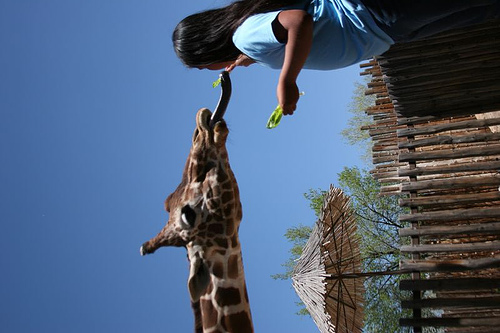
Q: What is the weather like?
A: It is clear.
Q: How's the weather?
A: It is clear.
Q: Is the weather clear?
A: Yes, it is clear.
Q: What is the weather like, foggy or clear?
A: It is clear.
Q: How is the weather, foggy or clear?
A: It is clear.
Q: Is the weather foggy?
A: No, it is clear.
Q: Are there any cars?
A: No, there are no cars.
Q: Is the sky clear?
A: Yes, the sky is clear.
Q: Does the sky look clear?
A: Yes, the sky is clear.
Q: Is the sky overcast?
A: No, the sky is clear.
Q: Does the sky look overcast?
A: No, the sky is clear.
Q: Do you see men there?
A: No, there are no men.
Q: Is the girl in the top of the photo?
A: Yes, the girl is in the top of the image.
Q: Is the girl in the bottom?
A: No, the girl is in the top of the image.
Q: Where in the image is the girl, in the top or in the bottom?
A: The girl is in the top of the image.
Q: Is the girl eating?
A: Yes, the girl is eating.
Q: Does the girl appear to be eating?
A: Yes, the girl is eating.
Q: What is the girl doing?
A: The girl is eating.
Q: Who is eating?
A: The girl is eating.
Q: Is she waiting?
A: No, the girl is eating.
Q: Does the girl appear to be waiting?
A: No, the girl is eating.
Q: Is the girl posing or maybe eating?
A: The girl is eating.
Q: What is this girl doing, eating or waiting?
A: The girl is eating.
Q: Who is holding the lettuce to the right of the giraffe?
A: The girl is holding the lettuce.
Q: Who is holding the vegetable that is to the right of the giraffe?
A: The girl is holding the lettuce.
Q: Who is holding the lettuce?
A: The girl is holding the lettuce.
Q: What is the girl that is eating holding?
A: The girl is holding the lettuce.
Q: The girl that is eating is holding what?
A: The girl is holding the lettuce.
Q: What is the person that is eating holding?
A: The girl is holding the lettuce.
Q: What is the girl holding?
A: The girl is holding the lettuce.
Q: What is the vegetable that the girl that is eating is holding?
A: The vegetable is lettuce.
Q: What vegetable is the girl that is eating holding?
A: The girl is holding the lettuce.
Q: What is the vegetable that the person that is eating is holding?
A: The vegetable is lettuce.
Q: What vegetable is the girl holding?
A: The girl is holding the lettuce.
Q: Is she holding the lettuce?
A: Yes, the girl is holding the lettuce.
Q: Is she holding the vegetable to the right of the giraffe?
A: Yes, the girl is holding the lettuce.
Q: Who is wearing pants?
A: The girl is wearing pants.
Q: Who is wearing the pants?
A: The girl is wearing pants.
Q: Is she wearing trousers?
A: Yes, the girl is wearing trousers.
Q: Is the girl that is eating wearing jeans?
A: No, the girl is wearing trousers.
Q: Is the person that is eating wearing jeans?
A: No, the girl is wearing trousers.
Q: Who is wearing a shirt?
A: The girl is wearing a shirt.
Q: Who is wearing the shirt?
A: The girl is wearing a shirt.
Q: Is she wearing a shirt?
A: Yes, the girl is wearing a shirt.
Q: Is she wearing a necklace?
A: No, the girl is wearing a shirt.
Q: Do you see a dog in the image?
A: No, there are no dogs.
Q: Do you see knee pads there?
A: No, there are no knee pads.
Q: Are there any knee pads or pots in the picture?
A: No, there are no knee pads or pots.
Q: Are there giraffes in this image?
A: Yes, there is a giraffe.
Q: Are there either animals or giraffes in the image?
A: Yes, there is a giraffe.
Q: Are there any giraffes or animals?
A: Yes, there is a giraffe.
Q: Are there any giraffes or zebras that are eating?
A: Yes, the giraffe is eating.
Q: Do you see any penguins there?
A: No, there are no penguins.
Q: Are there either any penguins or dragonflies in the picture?
A: No, there are no penguins or dragonflies.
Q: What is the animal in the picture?
A: The animal is a giraffe.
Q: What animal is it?
A: The animal is a giraffe.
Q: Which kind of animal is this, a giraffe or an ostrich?
A: That is a giraffe.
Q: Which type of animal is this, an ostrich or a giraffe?
A: That is a giraffe.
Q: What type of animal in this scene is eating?
A: The animal is a giraffe.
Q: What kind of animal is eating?
A: The animal is a giraffe.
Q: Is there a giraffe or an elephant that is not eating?
A: No, there is a giraffe but it is eating.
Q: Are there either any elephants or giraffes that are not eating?
A: No, there is a giraffe but it is eating.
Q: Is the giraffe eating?
A: Yes, the giraffe is eating.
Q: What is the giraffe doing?
A: The giraffe is eating.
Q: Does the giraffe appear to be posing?
A: No, the giraffe is eating.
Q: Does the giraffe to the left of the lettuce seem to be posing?
A: No, the giraffe is eating.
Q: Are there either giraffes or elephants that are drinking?
A: No, there is a giraffe but it is eating.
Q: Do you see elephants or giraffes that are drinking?
A: No, there is a giraffe but it is eating.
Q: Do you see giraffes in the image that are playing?
A: No, there is a giraffe but it is eating.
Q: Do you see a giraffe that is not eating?
A: No, there is a giraffe but it is eating.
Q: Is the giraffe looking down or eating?
A: The giraffe is eating.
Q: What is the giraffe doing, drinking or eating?
A: The giraffe is eating.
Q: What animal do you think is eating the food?
A: The giraffe is eating the food.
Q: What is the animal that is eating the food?
A: The animal is a giraffe.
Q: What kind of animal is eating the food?
A: The animal is a giraffe.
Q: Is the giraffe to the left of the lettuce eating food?
A: Yes, the giraffe is eating food.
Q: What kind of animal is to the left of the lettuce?
A: The animal is a giraffe.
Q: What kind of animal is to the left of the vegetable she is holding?
A: The animal is a giraffe.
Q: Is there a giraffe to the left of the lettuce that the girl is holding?
A: Yes, there is a giraffe to the left of the lettuce.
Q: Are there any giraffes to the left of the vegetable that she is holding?
A: Yes, there is a giraffe to the left of the lettuce.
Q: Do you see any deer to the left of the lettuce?
A: No, there is a giraffe to the left of the lettuce.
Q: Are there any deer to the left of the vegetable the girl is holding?
A: No, there is a giraffe to the left of the lettuce.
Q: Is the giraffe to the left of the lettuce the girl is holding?
A: Yes, the giraffe is to the left of the lettuce.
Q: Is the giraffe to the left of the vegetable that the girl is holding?
A: Yes, the giraffe is to the left of the lettuce.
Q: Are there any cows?
A: No, there are no cows.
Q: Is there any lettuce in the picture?
A: Yes, there is lettuce.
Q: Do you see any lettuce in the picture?
A: Yes, there is lettuce.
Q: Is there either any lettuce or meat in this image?
A: Yes, there is lettuce.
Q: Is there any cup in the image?
A: No, there are no cups.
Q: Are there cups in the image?
A: No, there are no cups.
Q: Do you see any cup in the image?
A: No, there are no cups.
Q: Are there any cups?
A: No, there are no cups.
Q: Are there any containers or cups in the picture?
A: No, there are no cups or containers.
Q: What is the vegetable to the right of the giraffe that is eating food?
A: The vegetable is lettuce.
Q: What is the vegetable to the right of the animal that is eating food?
A: The vegetable is lettuce.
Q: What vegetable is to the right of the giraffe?
A: The vegetable is lettuce.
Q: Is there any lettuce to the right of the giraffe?
A: Yes, there is lettuce to the right of the giraffe.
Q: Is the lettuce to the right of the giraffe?
A: Yes, the lettuce is to the right of the giraffe.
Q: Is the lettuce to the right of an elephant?
A: No, the lettuce is to the right of the giraffe.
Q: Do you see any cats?
A: No, there are no cats.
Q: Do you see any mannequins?
A: No, there are no mannequins.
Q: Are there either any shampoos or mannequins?
A: No, there are no mannequins or shampoos.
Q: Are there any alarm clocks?
A: No, there are no alarm clocks.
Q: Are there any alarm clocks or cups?
A: No, there are no alarm clocks or cups.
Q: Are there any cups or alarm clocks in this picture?
A: No, there are no alarm clocks or cups.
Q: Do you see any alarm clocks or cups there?
A: No, there are no alarm clocks or cups.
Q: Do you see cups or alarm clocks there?
A: No, there are no alarm clocks or cups.